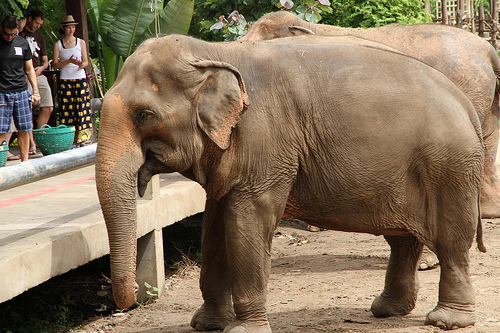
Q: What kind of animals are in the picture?
A: Elephants.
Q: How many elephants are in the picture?
A: Two.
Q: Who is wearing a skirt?
A: A woman.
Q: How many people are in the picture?
A: Three.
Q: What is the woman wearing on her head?
A: A hat.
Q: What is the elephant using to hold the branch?
A: Trunk.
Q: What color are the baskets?
A: Green.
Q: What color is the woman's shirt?
A: White.